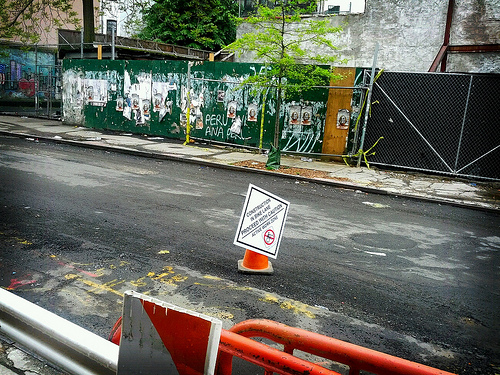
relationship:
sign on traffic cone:
[209, 182, 274, 257] [231, 178, 273, 281]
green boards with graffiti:
[47, 52, 328, 152] [0, 23, 62, 113]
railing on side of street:
[1, 286, 118, 371] [2, 134, 347, 371]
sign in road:
[220, 183, 290, 262] [0, 131, 499, 373]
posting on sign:
[262, 225, 274, 247] [220, 183, 290, 262]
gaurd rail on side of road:
[3, 275, 128, 371] [3, 134, 354, 373]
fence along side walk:
[373, 68, 496, 182] [18, 95, 498, 212]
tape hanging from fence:
[324, 73, 390, 169] [232, 60, 484, 181]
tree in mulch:
[222, 3, 348, 192] [230, 143, 332, 182]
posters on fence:
[220, 99, 328, 128] [16, 56, 496, 179]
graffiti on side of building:
[0, 23, 62, 113] [0, 0, 105, 103]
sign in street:
[220, 183, 290, 262] [0, 128, 498, 371]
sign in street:
[220, 183, 290, 262] [100, 163, 184, 255]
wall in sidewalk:
[78, 52, 343, 132] [1, 110, 498, 213]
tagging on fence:
[199, 111, 232, 140] [71, 64, 463, 140]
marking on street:
[12, 220, 187, 297] [12, 147, 494, 366]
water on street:
[441, 224, 498, 320] [0, 128, 498, 371]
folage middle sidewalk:
[216, 14, 336, 176] [356, 157, 452, 217]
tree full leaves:
[222, 3, 348, 192] [140, 2, 382, 117]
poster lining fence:
[88, 77, 110, 108] [53, 52, 496, 182]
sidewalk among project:
[1, 110, 498, 213] [8, 185, 479, 369]